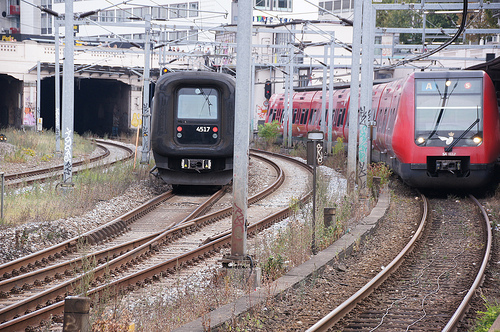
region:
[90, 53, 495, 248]
two trains are on the tracks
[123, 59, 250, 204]
the black train is on the left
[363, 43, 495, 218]
on the right is a red train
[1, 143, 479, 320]
three sets of tracks lay here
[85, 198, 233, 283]
this will allow a change of direction for the train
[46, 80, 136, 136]
a tunnel is in the background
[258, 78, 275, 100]
the trains traffic light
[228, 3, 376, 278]
support beams are in the train yard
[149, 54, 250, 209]
the end of the train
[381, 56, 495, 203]
the front of the train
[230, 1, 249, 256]
tall silver metal beam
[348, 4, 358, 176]
tall silver metal beam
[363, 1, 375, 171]
tall silver metal beam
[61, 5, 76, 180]
tall silver metal beam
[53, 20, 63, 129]
tall silver metal beam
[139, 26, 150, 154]
tall silver metal beam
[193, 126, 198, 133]
white number on train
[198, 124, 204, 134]
white number on train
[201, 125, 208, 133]
white number on train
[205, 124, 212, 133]
white number on train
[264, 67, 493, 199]
red train on tracks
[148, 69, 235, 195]
black train on the tracks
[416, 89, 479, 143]
windshield on the red train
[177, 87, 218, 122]
windshield on the black train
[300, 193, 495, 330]
train tracks on the ground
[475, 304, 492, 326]
patch of green grass on ground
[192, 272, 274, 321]
yellow weeds in grass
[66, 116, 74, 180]
graffitti on the pole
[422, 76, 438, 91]
A on the train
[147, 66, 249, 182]
matte black train car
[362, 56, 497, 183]
red train on the track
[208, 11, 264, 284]
metal pole with red graffiti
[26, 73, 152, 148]
dark train tunnel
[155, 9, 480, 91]
cables over the train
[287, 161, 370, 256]
grass growing between the tracks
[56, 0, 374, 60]
buildings behind the train tracks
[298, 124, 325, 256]
brown metal pole between tracks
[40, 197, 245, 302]
train tracks converge here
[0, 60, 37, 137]
dark train tunnel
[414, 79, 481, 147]
front window on a red train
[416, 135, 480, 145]
round white head lights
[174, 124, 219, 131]
round red head lights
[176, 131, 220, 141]
small gray circles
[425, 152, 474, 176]
black metal cattle guard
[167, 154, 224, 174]
black and silver cattle guard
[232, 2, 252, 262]
a gray metal pole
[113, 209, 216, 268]
the intersection of two tracks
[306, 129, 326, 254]
a meter between tracks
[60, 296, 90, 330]
a pole with the letter B on it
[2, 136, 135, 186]
rail road tracks that are empty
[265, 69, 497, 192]
red train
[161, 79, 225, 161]
rear side of the train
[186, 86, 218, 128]
rear window on the train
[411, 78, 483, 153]
big frontal window of the train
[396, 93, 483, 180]
red wagon of the train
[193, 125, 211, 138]
serial number of the train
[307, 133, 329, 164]
small rusty electric box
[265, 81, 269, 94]
red signal light in a pole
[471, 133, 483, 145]
right side light of the train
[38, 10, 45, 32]
glass window on building